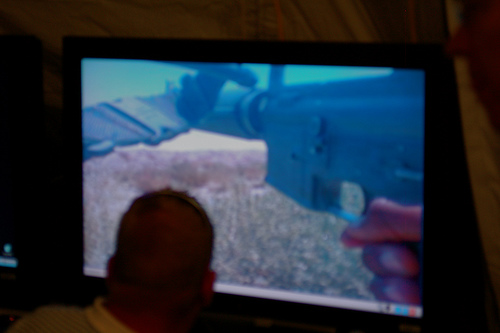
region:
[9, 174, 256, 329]
a man is watching tv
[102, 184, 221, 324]
the man has dark hair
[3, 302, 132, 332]
the man is wearing an orange shirt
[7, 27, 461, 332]
a large tv is in the room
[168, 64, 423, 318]
a person is holding a gun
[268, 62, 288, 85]
this piece is actually the sight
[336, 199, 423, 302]
the persons trigger finger is under the trigger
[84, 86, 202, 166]
this is part of a propeller blade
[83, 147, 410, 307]
the ground below is in the distance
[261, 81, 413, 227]
the gun is silver/blue in color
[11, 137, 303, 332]
a man that is inside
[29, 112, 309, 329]
a man that is watching tv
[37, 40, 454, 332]
a man that is watching television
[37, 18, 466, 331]
a large tv inside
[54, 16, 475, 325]
a large television inside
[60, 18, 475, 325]
a tv that is turned on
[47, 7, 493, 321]
a television that is turned on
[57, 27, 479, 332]
a man and a tv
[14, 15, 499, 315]
a man and a television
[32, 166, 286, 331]
a man wearing a yellow shirt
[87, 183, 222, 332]
the back of a man's head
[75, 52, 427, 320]
computer screen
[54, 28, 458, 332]
computer monitor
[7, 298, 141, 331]
striped yellow polo shirt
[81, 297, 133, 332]
the yellow collar of the polo shirt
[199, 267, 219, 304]
man's right ear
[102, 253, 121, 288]
man's left ear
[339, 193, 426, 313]
hand shown on the computer screen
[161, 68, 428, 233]
gun shown on the computer screen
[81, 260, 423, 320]
grey bar at the bottom of the computer screen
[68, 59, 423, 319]
A computer monitor in front of a man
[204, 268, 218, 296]
The right ear of the man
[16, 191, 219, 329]
A man looking at a monitor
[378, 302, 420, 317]
A display at the bottom of the monitor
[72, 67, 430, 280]
The monitor has a rectangular shape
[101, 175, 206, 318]
The man has no hair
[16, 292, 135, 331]
The man is wearing a yellow shirt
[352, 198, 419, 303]
A hand on the screen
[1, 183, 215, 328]
A man by a computer monitor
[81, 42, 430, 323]
The computer monitor is large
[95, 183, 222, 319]
a big head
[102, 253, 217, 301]
ears stick out on side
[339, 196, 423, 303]
one hand balled up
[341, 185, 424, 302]
the handle of gun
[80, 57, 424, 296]
a black gun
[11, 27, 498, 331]
a man watching tv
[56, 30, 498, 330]
a large tv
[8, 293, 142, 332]
a striped shirt on man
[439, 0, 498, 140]
a man standing up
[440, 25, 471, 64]
a pointy nose